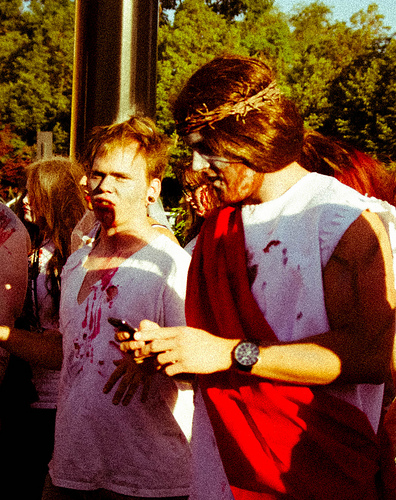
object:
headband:
[174, 78, 282, 136]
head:
[172, 55, 303, 203]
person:
[0, 157, 86, 499]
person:
[52, 111, 197, 499]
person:
[117, 57, 396, 499]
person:
[169, 154, 226, 248]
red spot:
[262, 240, 281, 255]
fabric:
[189, 171, 396, 500]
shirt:
[45, 223, 195, 497]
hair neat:
[80, 111, 171, 185]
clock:
[233, 341, 260, 369]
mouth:
[93, 197, 114, 210]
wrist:
[228, 338, 269, 378]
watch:
[230, 338, 260, 373]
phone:
[107, 316, 135, 340]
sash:
[187, 207, 396, 498]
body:
[184, 161, 395, 499]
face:
[235, 344, 258, 365]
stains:
[81, 285, 102, 337]